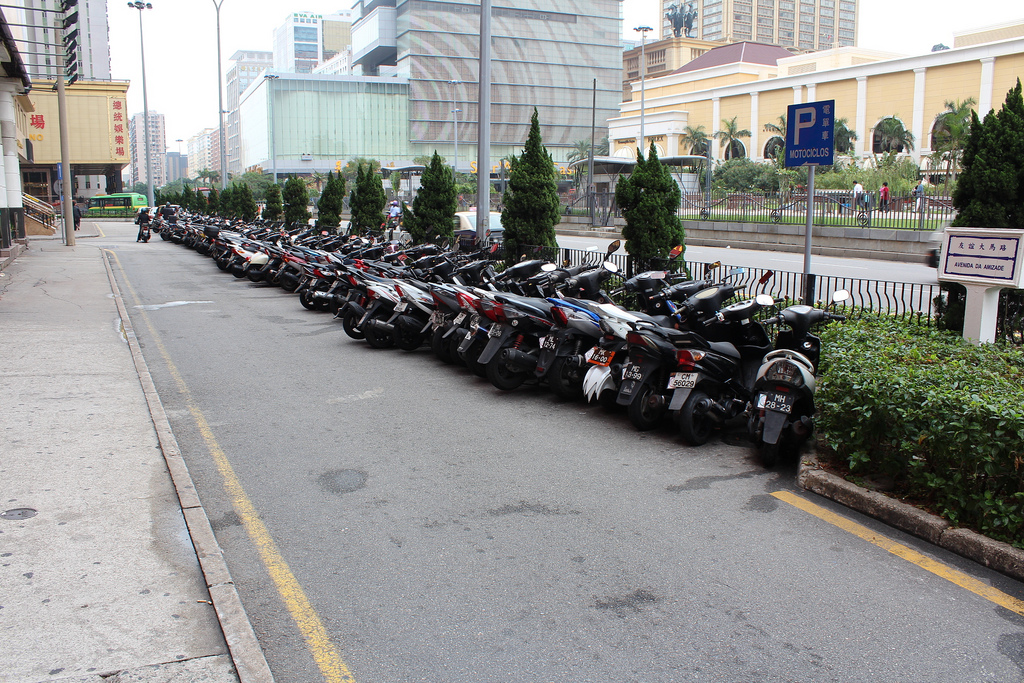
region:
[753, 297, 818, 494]
motorcycle on the road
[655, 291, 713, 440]
motorcycle on the road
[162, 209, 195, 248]
motorcycle on the road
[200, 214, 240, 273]
motorcycle on the road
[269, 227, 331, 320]
motorcycle on the road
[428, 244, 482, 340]
motorcycle on the road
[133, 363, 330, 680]
street curb and yellow painted line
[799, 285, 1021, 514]
green bushes by street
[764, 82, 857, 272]
a blue parking sign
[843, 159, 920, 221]
people walking in the distance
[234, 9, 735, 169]
large buildings in a downtown area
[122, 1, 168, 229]
street lamp on tall pole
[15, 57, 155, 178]
tan building with Asian writting on it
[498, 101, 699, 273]
bushes with pointed tops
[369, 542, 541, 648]
the street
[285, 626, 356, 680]
a yellow line in the street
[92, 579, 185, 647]
the sidewalk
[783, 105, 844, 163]
a sign that is blue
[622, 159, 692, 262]
a tall bush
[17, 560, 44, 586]
black marks on the ground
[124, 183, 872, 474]
a row of scooters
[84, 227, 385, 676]
yellow line on the ground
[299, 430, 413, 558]
spot on the ground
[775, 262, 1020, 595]
bush on the side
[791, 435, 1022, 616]
curb next to bush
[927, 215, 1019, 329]
a white and black sign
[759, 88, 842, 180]
blue and white sign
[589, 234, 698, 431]
black bikes lined up in lot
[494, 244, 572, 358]
black bikes lined up in lot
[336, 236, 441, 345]
black bikes lined up in lot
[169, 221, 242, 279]
black bikes lined up in lot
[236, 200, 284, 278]
black bikes lined up in lot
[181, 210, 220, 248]
bikes lined up in parking spots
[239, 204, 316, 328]
bikes lined up in parking spots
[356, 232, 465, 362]
bikes lined up in parking spots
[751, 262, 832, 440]
bikes lined up in parking spots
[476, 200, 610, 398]
bikes lined up in parking spots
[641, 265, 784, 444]
bikes lined up in parking spots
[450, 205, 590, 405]
bikes lined up in parking spots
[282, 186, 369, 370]
bikes lined up in parking spots